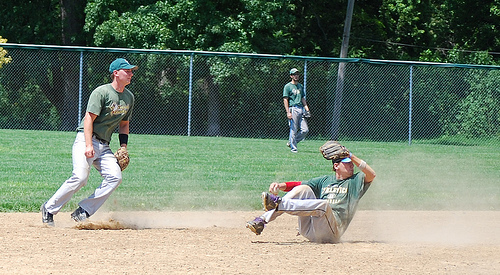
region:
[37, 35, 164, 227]
man in a green t shirt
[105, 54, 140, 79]
green baseball cap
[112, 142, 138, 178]
light tan baseball glove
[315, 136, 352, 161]
dark brown leather baseball glove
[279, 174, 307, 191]
red compression sleeve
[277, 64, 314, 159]
man in a green shirt standing in the grass playing baseball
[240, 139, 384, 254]
man sliding on the ground playing baseball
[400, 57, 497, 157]
grey and green metal fence in front of a bush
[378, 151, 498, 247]
cloud of dust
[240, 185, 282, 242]
black cleats with purple laces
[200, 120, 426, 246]
baseball player surrounded by dust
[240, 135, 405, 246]
ballplayer on ground with legs lifted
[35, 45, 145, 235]
player leaning forward with bent knees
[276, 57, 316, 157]
player standing in back watching action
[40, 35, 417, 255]
wire fence around the baseball field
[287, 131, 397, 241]
gloved hand lifted above head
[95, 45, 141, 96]
player wearing cap and looking forward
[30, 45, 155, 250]
dust being kicked up in front of shoe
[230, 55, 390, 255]
players looking in the same direction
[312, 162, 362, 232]
green shirt with yellow writing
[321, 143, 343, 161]
this is a glove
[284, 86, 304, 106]
this is a t shirt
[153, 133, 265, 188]
this is the grass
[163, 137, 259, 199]
the grass is green in color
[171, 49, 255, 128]
this is a fence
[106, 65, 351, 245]
these are players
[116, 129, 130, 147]
this is wristband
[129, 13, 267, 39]
these are leaves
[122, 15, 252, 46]
the leaves are green in color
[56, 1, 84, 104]
this is a tree trunk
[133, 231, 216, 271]
the dirt is brown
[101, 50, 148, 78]
the cap is blue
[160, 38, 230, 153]
the fence is metal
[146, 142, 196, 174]
the grass is green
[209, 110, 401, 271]
the man is slidding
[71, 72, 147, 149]
the shirt is green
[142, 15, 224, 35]
the leaves are green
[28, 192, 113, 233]
the man has shoes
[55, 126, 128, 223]
the pants are white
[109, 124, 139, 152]
the band is black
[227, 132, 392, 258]
Baseball player preparing to throw the ball.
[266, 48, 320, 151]
Outfield player observing infield players making a defensive play.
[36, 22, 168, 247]
Baseball player sliding to a stop on his feet.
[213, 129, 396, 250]
Baseball player sliding to a stop on his posterior.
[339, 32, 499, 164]
Large fence denoting end the of the baseball field.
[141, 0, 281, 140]
Large tree behind a fence.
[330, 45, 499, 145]
Chain link fence at the edge of the outfield.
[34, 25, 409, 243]
Three baseball players.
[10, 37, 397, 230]
Two infield players making a defensive play.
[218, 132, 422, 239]
Baseball player sliding and holding the baseball.